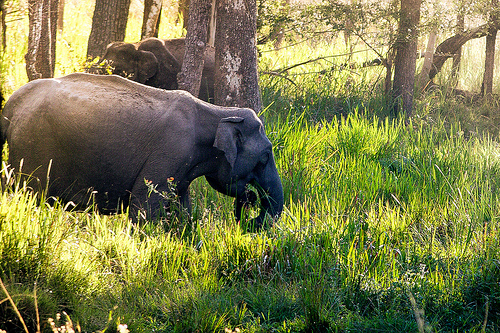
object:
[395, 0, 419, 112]
bark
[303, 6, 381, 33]
branches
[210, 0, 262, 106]
trunk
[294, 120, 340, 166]
grass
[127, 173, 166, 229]
leg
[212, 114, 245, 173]
ears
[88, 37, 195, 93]
elephant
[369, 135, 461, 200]
grass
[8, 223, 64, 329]
grass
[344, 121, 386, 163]
grass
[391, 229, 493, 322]
grass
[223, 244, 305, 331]
grass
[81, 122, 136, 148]
skin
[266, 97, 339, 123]
grass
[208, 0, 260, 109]
tree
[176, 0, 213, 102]
tree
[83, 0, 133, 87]
tree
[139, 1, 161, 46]
tree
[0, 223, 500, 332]
shadows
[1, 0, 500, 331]
grassy field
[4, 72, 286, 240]
elephant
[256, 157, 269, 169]
eye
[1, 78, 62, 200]
backside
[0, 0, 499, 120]
woods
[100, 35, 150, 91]
head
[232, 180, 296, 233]
trunk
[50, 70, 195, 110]
back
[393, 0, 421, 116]
tree